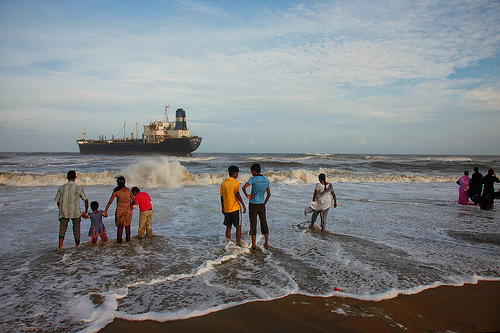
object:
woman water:
[300, 170, 347, 247]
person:
[51, 167, 88, 252]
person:
[103, 171, 137, 243]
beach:
[6, 231, 499, 331]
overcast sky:
[0, 2, 494, 154]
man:
[49, 162, 89, 253]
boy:
[239, 157, 276, 260]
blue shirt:
[246, 173, 274, 208]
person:
[242, 163, 269, 251]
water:
[0, 150, 495, 332]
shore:
[29, 216, 473, 331]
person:
[127, 184, 159, 243]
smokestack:
[175, 107, 186, 131]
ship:
[76, 101, 203, 156]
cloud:
[350, 96, 448, 129]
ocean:
[363, 183, 433, 267]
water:
[160, 252, 230, 299]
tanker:
[71, 100, 203, 163]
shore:
[2, 177, 494, 332]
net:
[292, 214, 316, 232]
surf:
[0, 164, 496, 321]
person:
[219, 163, 246, 243]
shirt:
[221, 177, 245, 221]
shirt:
[129, 181, 160, 243]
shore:
[33, 263, 497, 323]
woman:
[107, 176, 134, 242]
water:
[71, 162, 195, 193]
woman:
[302, 172, 342, 237]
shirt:
[308, 180, 338, 213]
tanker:
[70, 109, 205, 160]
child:
[129, 182, 156, 240]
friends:
[218, 151, 278, 258]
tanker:
[69, 104, 227, 169]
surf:
[47, 142, 311, 195]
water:
[12, 157, 477, 295]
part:
[164, 214, 184, 240]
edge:
[354, 278, 433, 305]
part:
[175, 199, 199, 246]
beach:
[12, 197, 489, 331]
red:
[133, 186, 156, 213]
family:
[44, 164, 164, 248]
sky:
[4, 8, 497, 159]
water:
[19, 228, 125, 295]